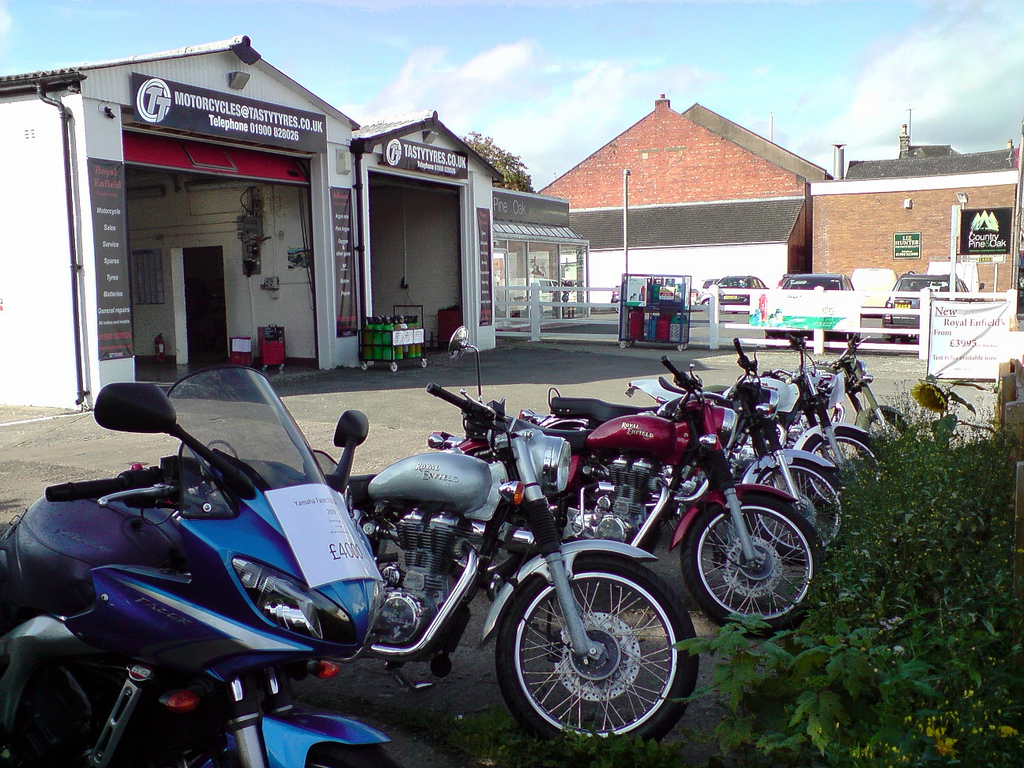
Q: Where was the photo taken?
A: At a bike store.